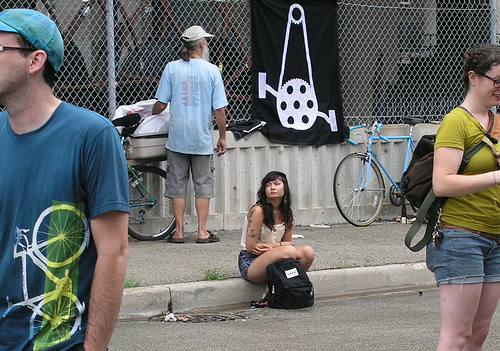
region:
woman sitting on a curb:
[220, 161, 320, 311]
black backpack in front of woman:
[255, 172, 317, 314]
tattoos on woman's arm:
[242, 201, 264, 248]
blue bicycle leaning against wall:
[325, 106, 431, 228]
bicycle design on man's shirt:
[0, 40, 124, 346]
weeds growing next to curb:
[118, 256, 228, 317]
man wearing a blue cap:
[0, 6, 70, 93]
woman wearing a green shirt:
[432, 42, 498, 235]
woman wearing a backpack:
[392, 48, 495, 250]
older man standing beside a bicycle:
[117, 16, 229, 247]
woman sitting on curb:
[228, 165, 323, 310]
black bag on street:
[257, 253, 320, 310]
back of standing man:
[148, 23, 226, 188]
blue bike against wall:
[325, 111, 426, 226]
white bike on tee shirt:
[9, 178, 106, 348]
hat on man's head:
[180, 20, 219, 55]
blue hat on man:
[8, 6, 65, 90]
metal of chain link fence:
[347, 23, 420, 90]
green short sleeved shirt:
[421, 106, 496, 231]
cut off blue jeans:
[423, 222, 495, 294]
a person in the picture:
[246, 159, 323, 270]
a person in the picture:
[1, 7, 133, 343]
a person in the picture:
[140, 29, 224, 235]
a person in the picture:
[438, 35, 499, 349]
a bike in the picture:
[327, 110, 429, 232]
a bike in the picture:
[121, 127, 172, 237]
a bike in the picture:
[0, 195, 91, 348]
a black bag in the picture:
[266, 260, 330, 318]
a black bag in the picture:
[395, 138, 437, 198]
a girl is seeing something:
[239, 156, 328, 321]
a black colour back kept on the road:
[258, 247, 338, 319]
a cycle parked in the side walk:
[334, 110, 454, 221]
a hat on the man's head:
[167, 7, 233, 74]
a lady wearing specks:
[464, 48, 499, 109]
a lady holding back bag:
[388, 80, 498, 228]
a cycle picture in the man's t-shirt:
[1, 188, 109, 349]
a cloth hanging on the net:
[246, 0, 358, 145]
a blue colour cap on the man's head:
[1, 2, 96, 69]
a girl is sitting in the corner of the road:
[238, 167, 338, 319]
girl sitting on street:
[227, 170, 341, 331]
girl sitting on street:
[215, 151, 295, 291]